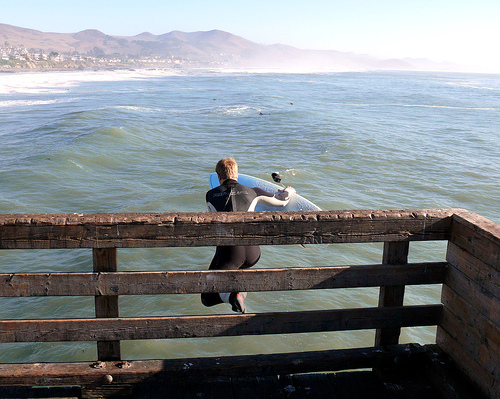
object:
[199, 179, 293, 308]
wetsuit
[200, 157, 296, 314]
human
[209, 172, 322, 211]
surf board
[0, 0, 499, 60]
sky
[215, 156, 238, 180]
hair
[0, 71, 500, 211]
body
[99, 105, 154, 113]
wave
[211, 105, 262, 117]
wave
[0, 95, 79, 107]
wave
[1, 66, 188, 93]
wave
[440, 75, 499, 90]
wave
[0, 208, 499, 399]
railing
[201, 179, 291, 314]
black arrow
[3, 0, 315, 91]
distance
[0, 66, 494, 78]
beach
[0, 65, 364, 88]
surf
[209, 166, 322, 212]
sharks ocean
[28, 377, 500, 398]
platform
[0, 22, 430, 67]
hills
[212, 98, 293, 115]
birds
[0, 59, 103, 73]
bank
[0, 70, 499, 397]
water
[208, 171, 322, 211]
blue board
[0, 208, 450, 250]
beam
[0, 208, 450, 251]
rail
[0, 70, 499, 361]
mounds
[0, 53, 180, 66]
homes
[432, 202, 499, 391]
wall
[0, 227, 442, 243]
lines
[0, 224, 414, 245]
cracks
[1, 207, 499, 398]
dock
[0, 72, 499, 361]
ocean